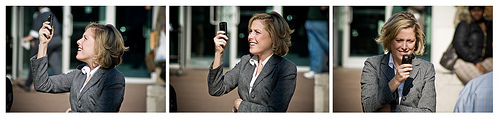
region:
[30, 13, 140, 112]
woman lifting up her cell phone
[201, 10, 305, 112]
woman looking at her mobile phone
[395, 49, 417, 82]
fingers wrapped around phone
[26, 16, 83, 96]
elbow bent at a 90 degree angle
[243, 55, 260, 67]
white color sticking out of tray jacket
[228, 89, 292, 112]
arm wrapped around front of body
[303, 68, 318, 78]
brught white shoe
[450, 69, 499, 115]
shoulder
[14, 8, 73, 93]
person wearing dark colors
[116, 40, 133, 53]
ends of hair flipping out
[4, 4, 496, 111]
a set of three photos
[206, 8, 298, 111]
a woman holding a cellphone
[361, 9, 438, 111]
a woman holding a cellphone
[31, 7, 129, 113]
a woman holding a cellphone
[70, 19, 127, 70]
a confused looking woman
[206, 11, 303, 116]
a woman wearing a grey suit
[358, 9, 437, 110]
a woman wearing a grey suit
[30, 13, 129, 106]
a woman wearing a grey suit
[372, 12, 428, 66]
a woman with blonde hair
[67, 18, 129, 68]
a woman with blonde hair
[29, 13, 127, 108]
a woman holding her black cellphone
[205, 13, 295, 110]
a woman holding her black cellphone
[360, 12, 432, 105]
a woman holding her black cellphone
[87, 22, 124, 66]
the blond hair of a woman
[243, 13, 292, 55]
the blond hair of a woman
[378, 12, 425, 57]
the blond hair of a woman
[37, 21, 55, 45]
the hand of a woman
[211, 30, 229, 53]
the hand of a woman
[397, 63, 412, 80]
the hand of a woman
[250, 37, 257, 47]
a woman's smile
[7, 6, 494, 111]
photo of woman with cell phone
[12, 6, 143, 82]
woman looking up at cell phone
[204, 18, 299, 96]
woman looking at face level at cell phone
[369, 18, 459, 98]
woman looking down at cell phone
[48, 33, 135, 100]
woman wearing grey sports jacket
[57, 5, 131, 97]
woman wearing white dress shirt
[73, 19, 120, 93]
collar on white dress shirt open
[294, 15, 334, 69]
person in blue jeans behind woman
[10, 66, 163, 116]
woman sitting on brown bench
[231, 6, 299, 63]
woman with short hair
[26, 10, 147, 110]
lady holding cell phone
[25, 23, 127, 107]
lady taking selfie picture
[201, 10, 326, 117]
lady smiling at phone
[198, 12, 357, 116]
lady wearing white collared shirt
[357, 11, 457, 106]
lady using cell phone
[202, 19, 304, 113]
lady wearing gray jacket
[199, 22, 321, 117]
gray jacket over white shirt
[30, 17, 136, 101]
right hand holding cell phone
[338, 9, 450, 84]
glass doors behind lady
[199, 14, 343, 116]
lady with left arm over waist